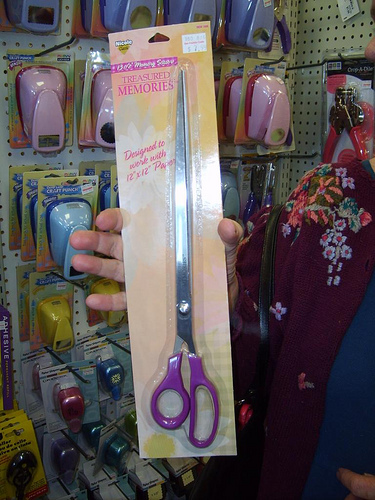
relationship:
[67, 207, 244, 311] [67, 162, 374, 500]
hand on lady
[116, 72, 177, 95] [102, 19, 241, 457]
letters on package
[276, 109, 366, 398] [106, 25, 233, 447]
lady holding scissors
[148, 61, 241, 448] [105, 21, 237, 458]
scissors in package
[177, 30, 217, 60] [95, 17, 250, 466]
tag on packaging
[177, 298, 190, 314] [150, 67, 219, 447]
metal piece on object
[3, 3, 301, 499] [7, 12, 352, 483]
objects hanging on wall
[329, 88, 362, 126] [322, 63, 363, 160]
metal part on object